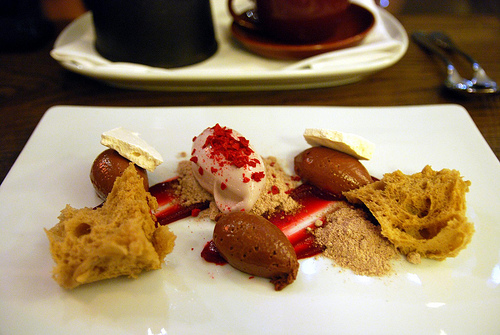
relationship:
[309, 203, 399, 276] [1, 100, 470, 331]
powder on plate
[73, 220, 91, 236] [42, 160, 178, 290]
hole in piece of food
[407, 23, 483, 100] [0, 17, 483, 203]
silverware on table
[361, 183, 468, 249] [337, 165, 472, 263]
piece of food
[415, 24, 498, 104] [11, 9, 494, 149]
silverware on table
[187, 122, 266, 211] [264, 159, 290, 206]
cream on top of crumbles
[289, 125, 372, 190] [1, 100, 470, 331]
food on plate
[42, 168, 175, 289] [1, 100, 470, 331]
food on plate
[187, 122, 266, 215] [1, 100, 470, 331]
cream on plate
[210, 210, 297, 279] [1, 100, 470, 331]
food on plate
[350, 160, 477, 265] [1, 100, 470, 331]
food on plate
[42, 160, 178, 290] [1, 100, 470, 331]
food on plate